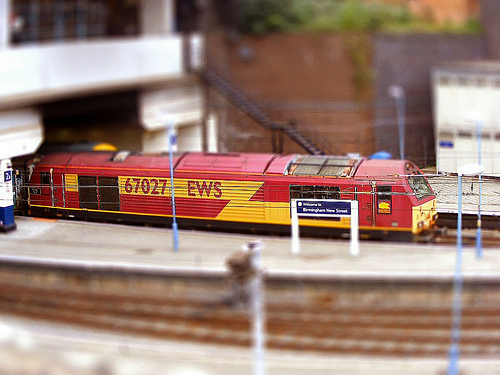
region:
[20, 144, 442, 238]
long toy red train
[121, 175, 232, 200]
numbers and letters on side of red train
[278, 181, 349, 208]
windows on side of train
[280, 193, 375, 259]
blue sign on white poles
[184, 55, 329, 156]
black ladder next to red train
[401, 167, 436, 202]
glass windshield on front of train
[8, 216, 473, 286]
train platform next to train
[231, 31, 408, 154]
red brick wall next to train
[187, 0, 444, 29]
green foliage on top of brick wall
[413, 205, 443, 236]
headlights on front of train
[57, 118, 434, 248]
a small toy train set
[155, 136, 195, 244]
a small toy street sign post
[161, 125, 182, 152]
a small toy street sign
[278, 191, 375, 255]
a small toy information sign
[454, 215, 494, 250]
a small toy train tracks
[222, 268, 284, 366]
a small blurry sign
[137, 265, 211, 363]
a bunch of train tracks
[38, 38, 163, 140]
the tunnel for a train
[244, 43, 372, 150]
a wall made of brick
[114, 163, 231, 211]
the number on a toy train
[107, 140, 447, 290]
the train is on truck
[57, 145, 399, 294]
the train s moving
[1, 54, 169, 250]
train is passing by the bridge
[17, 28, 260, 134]
the bridge is white in color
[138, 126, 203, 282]
the post is beside the railway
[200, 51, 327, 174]
the stair are made of metals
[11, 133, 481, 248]
train on the tracks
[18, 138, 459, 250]
yellow and red train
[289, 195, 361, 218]
blue and white sign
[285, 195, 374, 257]
two white posts on either side of the sign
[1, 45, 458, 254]
train coming out of a tunnel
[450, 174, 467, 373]
blue paint on the pole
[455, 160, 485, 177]
light on top of the pole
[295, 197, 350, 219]
white writing on a blue background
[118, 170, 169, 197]
red numbers on the side of the train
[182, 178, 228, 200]
red writing on the side of the train